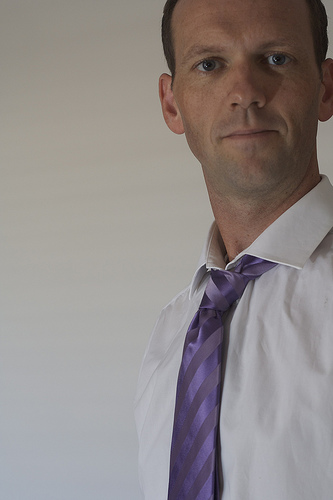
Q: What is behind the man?
A: A wall.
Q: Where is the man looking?
A: At the camera.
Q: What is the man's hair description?
A: A receding hairline.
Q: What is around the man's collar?
A: A tie.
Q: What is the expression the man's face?
A: Solemn.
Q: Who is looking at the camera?
A: The man in the white shirt and tie.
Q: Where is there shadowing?
A: On the man's nose.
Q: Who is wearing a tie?
A: The man in the white shirt.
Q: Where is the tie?
A: On the man's neck.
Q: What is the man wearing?
A: A dress shirt.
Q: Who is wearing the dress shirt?
A: The man.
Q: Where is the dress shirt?
A: On the man.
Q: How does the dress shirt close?
A: Buttons.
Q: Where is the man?
A: In front of a wall.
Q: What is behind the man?
A: A wall.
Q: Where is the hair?
A: ON the man's head.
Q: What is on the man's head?
A: Hair.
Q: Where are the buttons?
A: ON the shirt.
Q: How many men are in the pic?
A: 1.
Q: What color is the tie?
A: Purple.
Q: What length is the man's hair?
A: Short.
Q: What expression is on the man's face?
A: Neutral.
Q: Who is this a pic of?
A: A man.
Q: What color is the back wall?
A: White.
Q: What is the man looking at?
A: The camera.